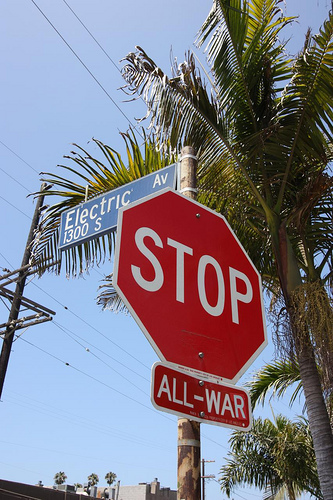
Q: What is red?
A: Stop sign.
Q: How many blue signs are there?
A: One.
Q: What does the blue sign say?
A: "Electric".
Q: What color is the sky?
A: Blue.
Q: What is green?
A: Leaves.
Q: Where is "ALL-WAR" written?
A: On bottom red sign.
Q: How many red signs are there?
A: Two.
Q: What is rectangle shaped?
A: Blue sign.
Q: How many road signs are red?
A: Two.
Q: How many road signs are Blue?
A: One.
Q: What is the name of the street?
A: Electric Av.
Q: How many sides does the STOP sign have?
A: Eight.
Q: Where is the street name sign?
A: Above the stop sign.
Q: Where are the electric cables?
A: In the air.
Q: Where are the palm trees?
A: Behind the signs.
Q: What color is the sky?
A: Blue.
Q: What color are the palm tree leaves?
A: Green.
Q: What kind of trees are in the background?
A: Palm trees.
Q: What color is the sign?
A: Red and white.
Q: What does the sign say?
A: Stop.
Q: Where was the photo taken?
A: Outside somewhere.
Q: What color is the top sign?
A: Blue.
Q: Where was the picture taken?
A: On a street next to a stop sign.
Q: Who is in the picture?
A: Nobody is in the picture.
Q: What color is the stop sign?
A: The stop sign is red.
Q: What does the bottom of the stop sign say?
A: It says all-war.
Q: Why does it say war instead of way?
A: Because somebody put a sticker over the word way.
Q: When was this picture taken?
A: It was taken in the day time.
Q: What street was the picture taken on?
A: It was taken on electric street.